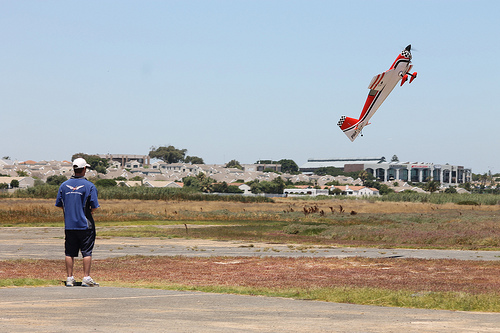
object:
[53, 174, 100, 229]
shirt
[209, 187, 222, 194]
green leaf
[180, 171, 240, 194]
plant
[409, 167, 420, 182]
window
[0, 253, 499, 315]
grass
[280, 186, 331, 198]
building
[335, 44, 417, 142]
plane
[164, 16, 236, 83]
air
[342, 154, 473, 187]
building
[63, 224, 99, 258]
black shorts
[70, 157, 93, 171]
hat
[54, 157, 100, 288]
man